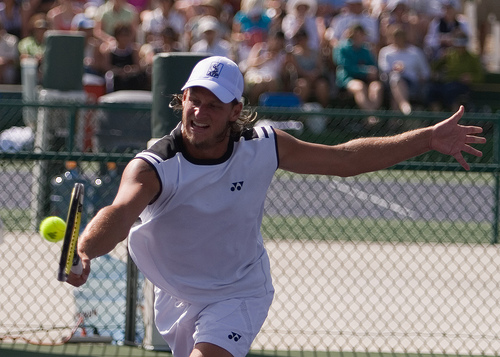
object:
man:
[67, 55, 486, 356]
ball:
[38, 216, 67, 242]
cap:
[180, 54, 243, 105]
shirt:
[129, 123, 276, 301]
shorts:
[153, 287, 275, 356]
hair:
[168, 93, 258, 135]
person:
[330, 23, 384, 124]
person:
[379, 25, 433, 122]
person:
[290, 32, 331, 108]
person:
[241, 31, 290, 104]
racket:
[56, 181, 85, 280]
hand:
[433, 105, 487, 173]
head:
[180, 55, 245, 146]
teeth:
[196, 122, 202, 124]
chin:
[189, 131, 208, 147]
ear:
[229, 102, 243, 122]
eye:
[190, 98, 200, 105]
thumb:
[449, 104, 465, 124]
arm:
[271, 125, 435, 176]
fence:
[1, 100, 499, 356]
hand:
[67, 254, 91, 287]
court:
[0, 157, 499, 356]